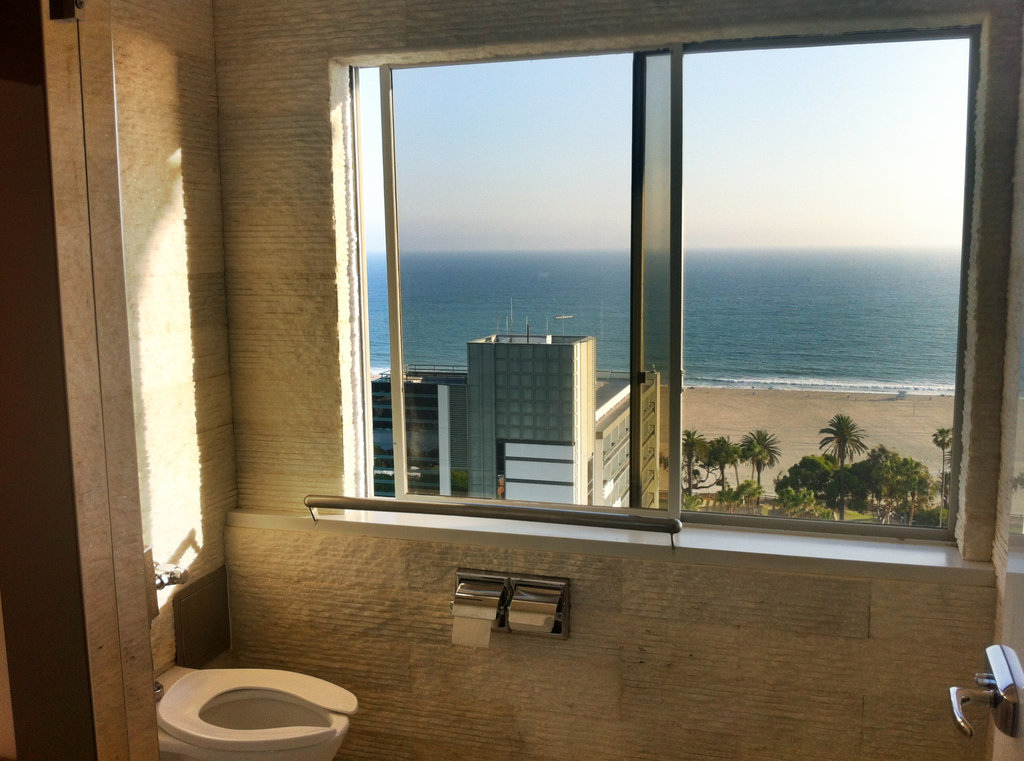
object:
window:
[342, 32, 974, 549]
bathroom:
[6, 2, 1021, 754]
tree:
[818, 411, 865, 520]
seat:
[154, 661, 358, 752]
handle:
[935, 662, 1004, 743]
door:
[904, 598, 1016, 759]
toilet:
[127, 650, 383, 761]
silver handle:
[940, 644, 1020, 753]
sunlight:
[135, 184, 225, 580]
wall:
[43, 1, 256, 721]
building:
[340, 321, 665, 521]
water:
[392, 234, 1024, 384]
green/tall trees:
[675, 411, 958, 518]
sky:
[337, 32, 990, 294]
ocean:
[311, 245, 975, 403]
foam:
[743, 373, 947, 400]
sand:
[707, 392, 905, 422]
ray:
[145, 206, 290, 519]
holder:
[428, 557, 596, 663]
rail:
[284, 482, 694, 566]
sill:
[351, 34, 985, 547]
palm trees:
[671, 410, 972, 568]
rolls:
[442, 575, 507, 650]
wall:
[221, 2, 999, 757]